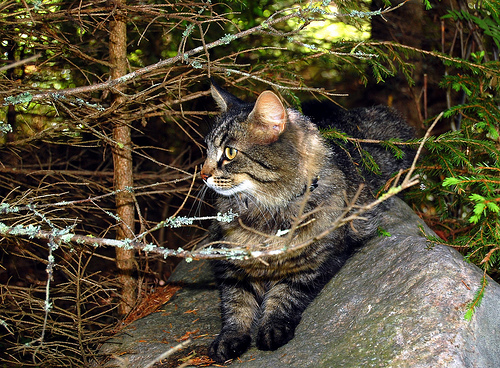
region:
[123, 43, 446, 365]
a cat on the rock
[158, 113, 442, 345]
a striped cat on rock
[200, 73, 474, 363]
a cat that is on a large rock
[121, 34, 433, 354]
a striped cat on a large rock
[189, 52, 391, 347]
a cat in woody area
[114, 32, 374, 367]
a striped cat in a woody area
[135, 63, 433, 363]
a cat that is outside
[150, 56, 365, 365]
a striped cat that is outside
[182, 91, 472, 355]
a cat laying outside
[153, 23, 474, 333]
a striped cat laying outside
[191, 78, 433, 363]
a cat on rock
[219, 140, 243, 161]
eye of a cat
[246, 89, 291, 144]
ear of a cat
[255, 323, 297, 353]
paw of a cat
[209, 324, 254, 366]
right paw of cat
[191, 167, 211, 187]
nose of a cat on a rock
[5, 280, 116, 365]
branches of a tree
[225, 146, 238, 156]
pupil of a cat on a rock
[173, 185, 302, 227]
whiskers of a cat on a rock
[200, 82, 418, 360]
grey striped cat sitting on rock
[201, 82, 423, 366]
black and grey cat laying on a rock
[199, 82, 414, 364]
black and grey striped cat resting on a rock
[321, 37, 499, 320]
evergreen tree branches with needles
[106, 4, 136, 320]
tree trunk standing in wooded area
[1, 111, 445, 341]
evergreen tree branch with no needles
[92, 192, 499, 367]
rock sitting on the ground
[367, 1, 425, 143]
tree trunk standing in wooded area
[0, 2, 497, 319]
trees in a wooded area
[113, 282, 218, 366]
fallen pine needles on a rock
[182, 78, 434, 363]
a cay laying on a rock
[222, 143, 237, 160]
the bright yellow eye of the cat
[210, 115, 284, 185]
striped fur on the cat's face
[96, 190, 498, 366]
a large rock in the middle of the woods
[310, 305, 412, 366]
moss growing on the rock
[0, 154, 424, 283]
a tree branch in front of the cat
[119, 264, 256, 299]
a shadow of the tree branch on the rock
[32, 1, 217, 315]
a small tree next to the cat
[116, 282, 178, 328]
dried pine needles on the ground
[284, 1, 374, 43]
light shining through the trees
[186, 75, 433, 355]
cat sitting on a rock outside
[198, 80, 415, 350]
beige gray and black cat sitting on a rock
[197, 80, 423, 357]
striped cat sitting on a gray rock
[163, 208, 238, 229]
leaves trying to grow on a barren branch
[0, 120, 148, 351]
many branches missing leaves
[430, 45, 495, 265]
branches bearing many little green leaves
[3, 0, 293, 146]
trees of the forest in the background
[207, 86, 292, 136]
alert cat ears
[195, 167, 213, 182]
black rimmed pink cat nose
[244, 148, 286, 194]
black markings on the cat